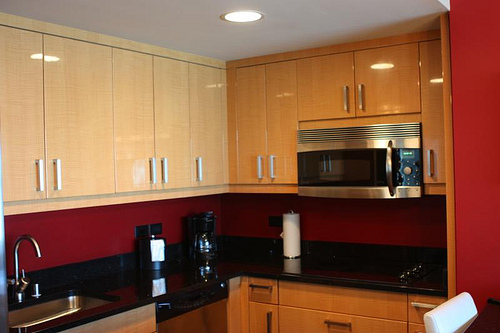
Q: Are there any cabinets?
A: Yes, there is a cabinet.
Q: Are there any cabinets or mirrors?
A: Yes, there is a cabinet.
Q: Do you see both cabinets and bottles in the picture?
A: No, there is a cabinet but no bottles.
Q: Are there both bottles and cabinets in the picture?
A: No, there is a cabinet but no bottles.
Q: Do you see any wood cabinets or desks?
A: Yes, there is a wood cabinet.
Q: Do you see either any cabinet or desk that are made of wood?
A: Yes, the cabinet is made of wood.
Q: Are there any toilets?
A: No, there are no toilets.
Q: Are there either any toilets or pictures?
A: No, there are no toilets or pictures.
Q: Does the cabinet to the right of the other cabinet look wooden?
A: Yes, the cabinet is wooden.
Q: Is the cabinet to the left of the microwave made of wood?
A: Yes, the cabinet is made of wood.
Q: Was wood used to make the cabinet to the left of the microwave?
A: Yes, the cabinet is made of wood.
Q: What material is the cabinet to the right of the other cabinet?
A: The cabinet is made of wood.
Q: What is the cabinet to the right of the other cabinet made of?
A: The cabinet is made of wood.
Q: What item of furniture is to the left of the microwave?
A: The piece of furniture is a cabinet.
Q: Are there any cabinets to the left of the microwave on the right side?
A: Yes, there is a cabinet to the left of the microwave.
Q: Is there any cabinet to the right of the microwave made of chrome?
A: No, the cabinet is to the left of the microwave.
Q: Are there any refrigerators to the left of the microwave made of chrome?
A: No, there is a cabinet to the left of the microwave.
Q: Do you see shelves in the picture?
A: No, there are no shelves.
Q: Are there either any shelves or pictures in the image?
A: No, there are no shelves or pictures.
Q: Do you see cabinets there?
A: Yes, there is a cabinet.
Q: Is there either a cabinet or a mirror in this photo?
A: Yes, there is a cabinet.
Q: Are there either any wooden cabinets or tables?
A: Yes, there is a wood cabinet.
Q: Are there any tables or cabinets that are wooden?
A: Yes, the cabinet is wooden.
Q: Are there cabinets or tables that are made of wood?
A: Yes, the cabinet is made of wood.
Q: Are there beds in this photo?
A: No, there are no beds.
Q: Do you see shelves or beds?
A: No, there are no beds or shelves.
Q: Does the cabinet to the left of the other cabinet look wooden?
A: Yes, the cabinet is wooden.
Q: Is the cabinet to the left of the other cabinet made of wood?
A: Yes, the cabinet is made of wood.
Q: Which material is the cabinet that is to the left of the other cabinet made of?
A: The cabinet is made of wood.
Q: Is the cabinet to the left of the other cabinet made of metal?
A: No, the cabinet is made of wood.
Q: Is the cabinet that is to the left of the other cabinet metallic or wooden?
A: The cabinet is wooden.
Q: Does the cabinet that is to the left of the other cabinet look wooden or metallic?
A: The cabinet is wooden.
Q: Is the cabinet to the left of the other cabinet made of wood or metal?
A: The cabinet is made of wood.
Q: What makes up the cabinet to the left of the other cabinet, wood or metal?
A: The cabinet is made of wood.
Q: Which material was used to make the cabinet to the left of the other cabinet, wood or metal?
A: The cabinet is made of wood.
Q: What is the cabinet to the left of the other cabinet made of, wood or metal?
A: The cabinet is made of wood.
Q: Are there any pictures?
A: No, there are no pictures.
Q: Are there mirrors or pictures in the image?
A: No, there are no pictures or mirrors.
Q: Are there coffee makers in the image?
A: Yes, there is a coffee maker.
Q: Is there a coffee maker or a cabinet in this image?
A: Yes, there is a coffee maker.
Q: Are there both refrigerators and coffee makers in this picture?
A: No, there is a coffee maker but no refrigerators.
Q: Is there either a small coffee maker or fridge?
A: Yes, there is a small coffee maker.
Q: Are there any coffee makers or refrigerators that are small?
A: Yes, the coffee maker is small.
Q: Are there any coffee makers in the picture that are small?
A: Yes, there is a small coffee maker.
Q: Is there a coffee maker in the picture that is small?
A: Yes, there is a coffee maker that is small.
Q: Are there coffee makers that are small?
A: Yes, there is a coffee maker that is small.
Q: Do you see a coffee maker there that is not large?
A: Yes, there is a small coffee maker.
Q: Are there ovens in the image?
A: No, there are no ovens.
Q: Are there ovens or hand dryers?
A: No, there are no ovens or hand dryers.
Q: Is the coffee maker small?
A: Yes, the coffee maker is small.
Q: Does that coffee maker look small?
A: Yes, the coffee maker is small.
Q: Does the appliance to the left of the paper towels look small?
A: Yes, the coffee maker is small.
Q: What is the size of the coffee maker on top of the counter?
A: The coffee machine is small.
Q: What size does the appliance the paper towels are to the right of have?
A: The coffee machine has small size.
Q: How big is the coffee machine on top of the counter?
A: The coffee maker is small.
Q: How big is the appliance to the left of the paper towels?
A: The coffee maker is small.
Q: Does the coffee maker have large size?
A: No, the coffee maker is small.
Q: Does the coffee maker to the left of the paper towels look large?
A: No, the coffee maker is small.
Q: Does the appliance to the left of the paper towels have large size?
A: No, the coffee maker is small.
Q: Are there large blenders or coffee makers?
A: No, there is a coffee maker but it is small.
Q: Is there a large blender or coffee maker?
A: No, there is a coffee maker but it is small.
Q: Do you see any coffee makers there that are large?
A: No, there is a coffee maker but it is small.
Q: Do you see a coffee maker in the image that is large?
A: No, there is a coffee maker but it is small.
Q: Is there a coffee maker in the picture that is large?
A: No, there is a coffee maker but it is small.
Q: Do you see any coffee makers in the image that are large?
A: No, there is a coffee maker but it is small.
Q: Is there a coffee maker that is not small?
A: No, there is a coffee maker but it is small.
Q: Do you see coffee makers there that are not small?
A: No, there is a coffee maker but it is small.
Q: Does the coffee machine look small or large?
A: The coffee machine is small.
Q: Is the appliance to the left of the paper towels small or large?
A: The coffee machine is small.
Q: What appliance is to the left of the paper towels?
A: The appliance is a coffee maker.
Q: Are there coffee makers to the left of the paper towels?
A: Yes, there is a coffee maker to the left of the paper towels.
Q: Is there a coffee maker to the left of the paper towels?
A: Yes, there is a coffee maker to the left of the paper towels.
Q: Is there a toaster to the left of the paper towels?
A: No, there is a coffee maker to the left of the paper towels.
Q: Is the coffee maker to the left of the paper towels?
A: Yes, the coffee maker is to the left of the paper towels.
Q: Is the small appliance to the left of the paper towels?
A: Yes, the coffee maker is to the left of the paper towels.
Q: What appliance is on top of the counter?
A: The appliance is a coffee maker.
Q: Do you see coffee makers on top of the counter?
A: Yes, there is a coffee maker on top of the counter.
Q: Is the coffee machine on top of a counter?
A: Yes, the coffee machine is on top of a counter.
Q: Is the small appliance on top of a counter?
A: Yes, the coffee machine is on top of a counter.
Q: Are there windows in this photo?
A: Yes, there is a window.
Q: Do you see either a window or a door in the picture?
A: Yes, there is a window.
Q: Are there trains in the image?
A: No, there are no trains.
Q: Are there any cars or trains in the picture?
A: No, there are no trains or cars.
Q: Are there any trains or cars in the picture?
A: No, there are no trains or cars.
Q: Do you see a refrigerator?
A: No, there are no refrigerators.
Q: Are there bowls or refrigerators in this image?
A: No, there are no refrigerators or bowls.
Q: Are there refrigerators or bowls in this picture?
A: No, there are no refrigerators or bowls.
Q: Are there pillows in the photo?
A: No, there are no pillows.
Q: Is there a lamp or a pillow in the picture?
A: No, there are no pillows or lamps.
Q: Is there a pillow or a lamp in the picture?
A: No, there are no pillows or lamps.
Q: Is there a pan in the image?
A: No, there are no pans.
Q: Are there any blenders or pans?
A: No, there are no pans or blenders.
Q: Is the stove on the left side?
A: No, the stove is on the right of the image.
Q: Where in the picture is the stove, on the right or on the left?
A: The stove is on the right of the image.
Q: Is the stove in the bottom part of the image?
A: Yes, the stove is in the bottom of the image.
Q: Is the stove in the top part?
A: No, the stove is in the bottom of the image.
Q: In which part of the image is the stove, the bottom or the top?
A: The stove is in the bottom of the image.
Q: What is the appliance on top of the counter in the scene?
A: The appliance is a stove.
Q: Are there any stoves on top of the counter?
A: Yes, there is a stove on top of the counter.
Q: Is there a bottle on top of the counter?
A: No, there is a stove on top of the counter.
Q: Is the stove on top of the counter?
A: Yes, the stove is on top of the counter.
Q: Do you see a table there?
A: Yes, there is a table.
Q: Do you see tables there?
A: Yes, there is a table.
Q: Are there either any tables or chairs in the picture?
A: Yes, there is a table.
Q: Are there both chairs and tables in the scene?
A: Yes, there are both a table and a chair.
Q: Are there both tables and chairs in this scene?
A: Yes, there are both a table and a chair.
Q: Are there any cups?
A: No, there are no cups.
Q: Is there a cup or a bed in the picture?
A: No, there are no cups or beds.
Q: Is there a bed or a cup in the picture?
A: No, there are no cups or beds.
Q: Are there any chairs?
A: Yes, there is a chair.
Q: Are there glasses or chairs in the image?
A: Yes, there is a chair.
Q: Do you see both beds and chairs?
A: No, there is a chair but no beds.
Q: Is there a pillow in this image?
A: No, there are no pillows.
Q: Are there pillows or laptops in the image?
A: No, there are no pillows or laptops.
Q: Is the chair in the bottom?
A: Yes, the chair is in the bottom of the image.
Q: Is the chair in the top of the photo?
A: No, the chair is in the bottom of the image.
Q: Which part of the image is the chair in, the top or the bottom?
A: The chair is in the bottom of the image.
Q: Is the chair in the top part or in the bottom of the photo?
A: The chair is in the bottom of the image.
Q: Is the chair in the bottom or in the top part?
A: The chair is in the bottom of the image.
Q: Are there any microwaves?
A: Yes, there is a microwave.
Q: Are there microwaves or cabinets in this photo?
A: Yes, there is a microwave.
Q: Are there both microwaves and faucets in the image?
A: Yes, there are both a microwave and a faucet.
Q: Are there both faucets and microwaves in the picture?
A: Yes, there are both a microwave and a faucet.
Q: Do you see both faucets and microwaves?
A: Yes, there are both a microwave and a faucet.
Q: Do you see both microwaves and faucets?
A: Yes, there are both a microwave and a faucet.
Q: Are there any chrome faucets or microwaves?
A: Yes, there is a chrome microwave.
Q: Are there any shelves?
A: No, there are no shelves.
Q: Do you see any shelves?
A: No, there are no shelves.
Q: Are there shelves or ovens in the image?
A: No, there are no shelves or ovens.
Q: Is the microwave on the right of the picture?
A: Yes, the microwave is on the right of the image.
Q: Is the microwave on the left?
A: No, the microwave is on the right of the image.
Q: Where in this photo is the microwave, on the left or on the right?
A: The microwave is on the right of the image.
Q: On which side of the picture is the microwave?
A: The microwave is on the right of the image.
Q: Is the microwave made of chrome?
A: Yes, the microwave is made of chrome.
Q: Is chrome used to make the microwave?
A: Yes, the microwave is made of chrome.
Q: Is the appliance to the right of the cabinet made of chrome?
A: Yes, the microwave is made of chrome.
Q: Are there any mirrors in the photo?
A: No, there are no mirrors.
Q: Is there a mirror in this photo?
A: No, there are no mirrors.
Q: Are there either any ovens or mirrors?
A: No, there are no mirrors or ovens.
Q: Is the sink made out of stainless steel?
A: Yes, the sink is made of stainless steel.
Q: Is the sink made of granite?
A: No, the sink is made of stainless steel.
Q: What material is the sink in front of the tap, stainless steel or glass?
A: The sink is made of stainless steel.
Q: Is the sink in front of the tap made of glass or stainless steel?
A: The sink is made of stainless steel.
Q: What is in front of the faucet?
A: The sink is in front of the faucet.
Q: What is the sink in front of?
A: The sink is in front of the faucet.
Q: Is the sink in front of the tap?
A: Yes, the sink is in front of the tap.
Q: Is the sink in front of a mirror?
A: No, the sink is in front of the tap.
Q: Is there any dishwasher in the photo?
A: Yes, there is a dishwasher.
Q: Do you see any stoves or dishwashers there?
A: Yes, there is a dishwasher.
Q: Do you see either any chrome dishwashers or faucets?
A: Yes, there is a chrome dishwasher.